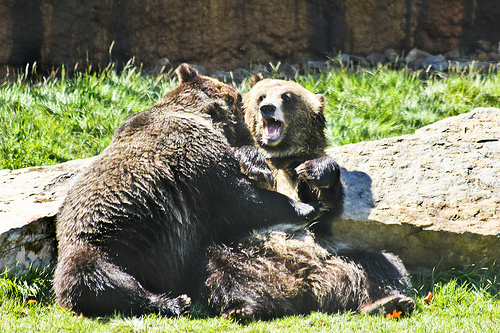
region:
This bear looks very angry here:
[266, 88, 293, 195]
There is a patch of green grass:
[441, 288, 452, 317]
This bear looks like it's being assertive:
[116, 105, 154, 227]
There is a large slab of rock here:
[411, 133, 443, 229]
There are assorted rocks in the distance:
[304, 58, 314, 75]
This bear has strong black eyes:
[283, 86, 293, 99]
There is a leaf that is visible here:
[16, 290, 28, 312]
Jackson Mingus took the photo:
[110, 103, 171, 282]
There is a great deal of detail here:
[113, 56, 178, 321]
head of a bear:
[237, 66, 332, 167]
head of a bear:
[163, 35, 250, 142]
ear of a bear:
[172, 61, 217, 88]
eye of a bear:
[253, 91, 284, 106]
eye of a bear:
[280, 85, 311, 107]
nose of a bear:
[257, 101, 285, 116]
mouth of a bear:
[255, 112, 289, 139]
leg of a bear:
[43, 216, 155, 313]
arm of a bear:
[153, 129, 240, 203]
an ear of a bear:
[169, 52, 217, 87]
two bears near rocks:
[80, 69, 380, 331]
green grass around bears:
[416, 274, 487, 326]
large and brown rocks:
[340, 133, 495, 230]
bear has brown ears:
[244, 56, 366, 89]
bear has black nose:
[255, 81, 288, 129]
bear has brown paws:
[282, 129, 338, 204]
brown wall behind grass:
[18, 2, 373, 66]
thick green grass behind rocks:
[6, 61, 128, 161]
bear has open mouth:
[248, 99, 288, 146]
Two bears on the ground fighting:
[59, 52, 419, 331]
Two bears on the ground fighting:
[64, 60, 434, 317]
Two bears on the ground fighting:
[43, 47, 424, 331]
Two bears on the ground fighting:
[52, 60, 427, 323]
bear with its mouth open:
[248, 101, 295, 151]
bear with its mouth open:
[248, 116, 285, 137]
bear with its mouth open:
[253, 95, 290, 154]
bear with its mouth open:
[260, 97, 283, 148]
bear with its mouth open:
[251, 103, 292, 144]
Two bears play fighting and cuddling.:
[53, 61, 410, 322]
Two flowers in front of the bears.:
[380, 285, 440, 322]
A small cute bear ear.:
[165, 58, 204, 92]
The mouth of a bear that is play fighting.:
[257, 111, 285, 143]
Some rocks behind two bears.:
[152, 42, 495, 84]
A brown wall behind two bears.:
[0, 2, 497, 82]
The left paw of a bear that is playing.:
[292, 155, 333, 186]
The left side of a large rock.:
[0, 149, 112, 276]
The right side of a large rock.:
[319, 108, 499, 278]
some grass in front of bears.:
[2, 263, 499, 330]